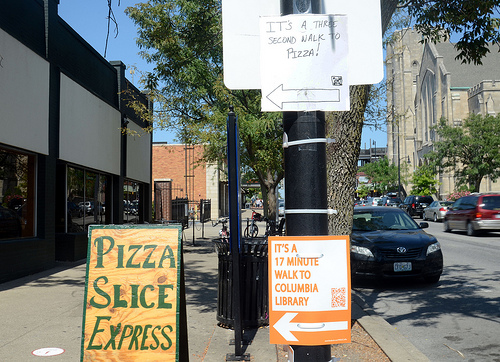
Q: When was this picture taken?
A: Daytime.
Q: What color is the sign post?
A: Black.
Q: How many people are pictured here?
A: Zero.